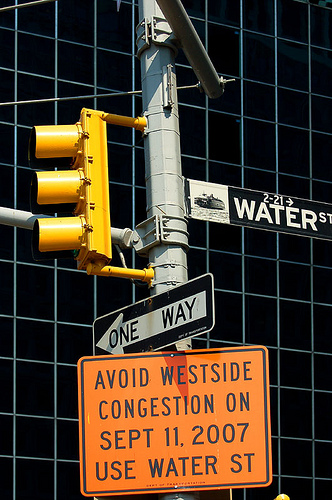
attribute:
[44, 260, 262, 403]
sign — black, white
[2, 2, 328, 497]
building — black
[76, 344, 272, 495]
sign — orange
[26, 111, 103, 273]
signal — yellow, traffic